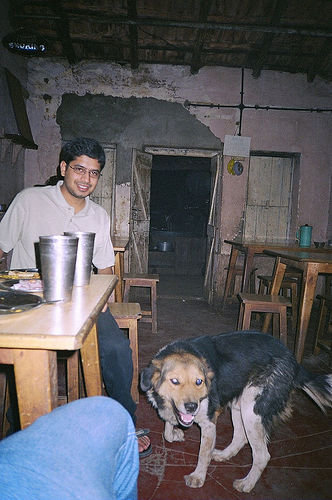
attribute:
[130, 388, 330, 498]
floor — red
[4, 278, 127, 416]
table — white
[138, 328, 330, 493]
dog — black and brown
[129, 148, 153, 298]
door — open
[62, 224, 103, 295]
cup — tall, silver, metal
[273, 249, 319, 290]
table — brown, wooden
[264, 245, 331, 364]
table — brown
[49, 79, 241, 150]
paint — peeled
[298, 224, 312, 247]
jug — green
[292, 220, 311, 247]
pitcher — small, green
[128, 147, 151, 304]
door — brown, white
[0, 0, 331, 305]
building — small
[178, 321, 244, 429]
dog — brown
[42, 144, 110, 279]
man — sitting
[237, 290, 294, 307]
seat — square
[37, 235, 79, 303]
cup — metal, silver, all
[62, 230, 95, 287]
cup — silver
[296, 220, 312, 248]
container — blue